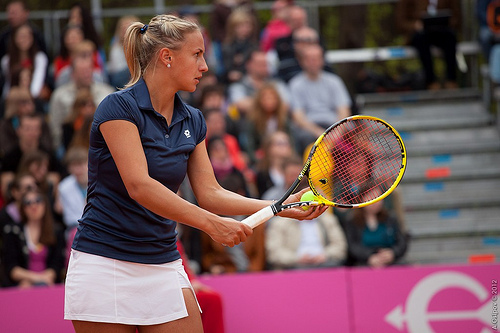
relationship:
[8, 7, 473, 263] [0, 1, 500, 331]
people in stands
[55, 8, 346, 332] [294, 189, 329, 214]
woman holding ball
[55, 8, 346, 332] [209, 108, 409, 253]
woman holding racket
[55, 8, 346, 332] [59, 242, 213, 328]
woman in skirt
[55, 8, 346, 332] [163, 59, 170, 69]
woman in earring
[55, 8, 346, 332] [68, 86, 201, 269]
woman in shirt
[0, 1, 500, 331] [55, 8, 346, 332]
stands behind woman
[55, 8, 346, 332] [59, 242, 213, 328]
woman wearing skirt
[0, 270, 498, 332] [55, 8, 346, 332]
wall behind woman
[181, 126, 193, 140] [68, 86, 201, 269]
logo on shirt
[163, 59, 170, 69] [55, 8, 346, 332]
earring on woman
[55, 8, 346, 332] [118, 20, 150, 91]
woman in ponytail